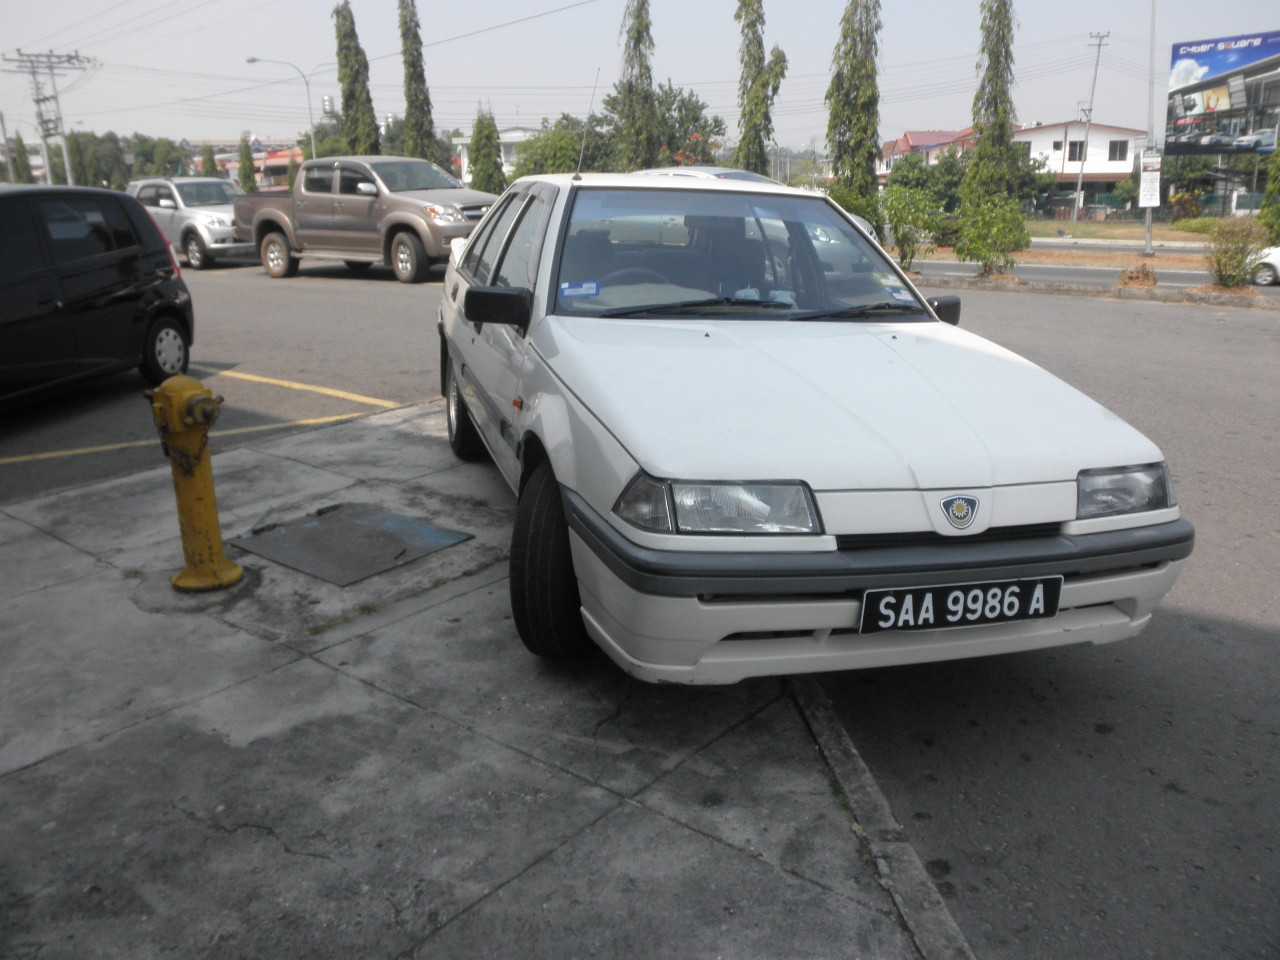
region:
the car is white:
[433, 72, 1197, 697]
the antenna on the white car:
[446, 62, 1199, 687]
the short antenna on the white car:
[437, 61, 1197, 688]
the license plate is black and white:
[861, 574, 1062, 636]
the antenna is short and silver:
[570, 64, 608, 177]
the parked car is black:
[3, 181, 195, 418]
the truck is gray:
[232, 150, 502, 278]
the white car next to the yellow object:
[142, 95, 1193, 681]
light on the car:
[607, 452, 786, 547]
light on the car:
[1077, 468, 1161, 526]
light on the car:
[420, 189, 463, 227]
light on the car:
[212, 214, 241, 232]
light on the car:
[157, 243, 186, 279]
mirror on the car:
[457, 284, 546, 326]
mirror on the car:
[930, 282, 961, 325]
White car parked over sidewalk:
[433, 164, 1202, 694]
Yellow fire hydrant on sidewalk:
[146, 368, 261, 605]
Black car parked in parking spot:
[5, 184, 204, 436]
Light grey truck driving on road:
[228, 149, 504, 286]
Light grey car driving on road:
[120, 167, 251, 267]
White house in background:
[879, 111, 1169, 217]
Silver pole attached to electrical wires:
[3, 37, 105, 197]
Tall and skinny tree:
[954, 6, 1038, 293]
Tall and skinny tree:
[824, 1, 898, 249]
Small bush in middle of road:
[1201, 209, 1265, 294]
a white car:
[451, 177, 1202, 692]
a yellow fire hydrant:
[138, 384, 266, 596]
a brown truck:
[248, 153, 456, 255]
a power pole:
[14, 32, 87, 178]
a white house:
[896, 120, 1135, 204]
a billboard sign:
[1170, 36, 1270, 178]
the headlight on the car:
[623, 473, 796, 524]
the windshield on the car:
[546, 188, 902, 316]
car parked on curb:
[437, 176, 1197, 956]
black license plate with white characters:
[858, 574, 1062, 638]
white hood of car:
[527, 325, 1163, 493]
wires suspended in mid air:
[0, 9, 1274, 133]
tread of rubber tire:
[510, 463, 575, 664]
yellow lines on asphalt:
[2, 357, 407, 464]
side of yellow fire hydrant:
[148, 373, 250, 590]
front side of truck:
[234, 150, 506, 281]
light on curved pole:
[243, 52, 332, 154]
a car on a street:
[410, 170, 1183, 698]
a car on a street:
[19, 193, 216, 394]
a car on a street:
[127, 162, 276, 277]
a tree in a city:
[966, 5, 1048, 264]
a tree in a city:
[394, 0, 452, 162]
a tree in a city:
[324, 3, 391, 173]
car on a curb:
[388, 126, 1234, 766]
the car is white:
[432, 152, 1198, 790]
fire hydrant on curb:
[117, 346, 338, 620]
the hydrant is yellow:
[110, 368, 312, 658]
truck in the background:
[220, 112, 488, 309]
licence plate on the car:
[832, 569, 1075, 660]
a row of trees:
[305, 6, 1091, 243]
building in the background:
[927, 95, 1162, 226]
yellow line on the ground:
[212, 306, 400, 432]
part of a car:
[490, 439, 583, 663]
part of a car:
[609, 457, 824, 563]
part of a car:
[1070, 452, 1176, 526]